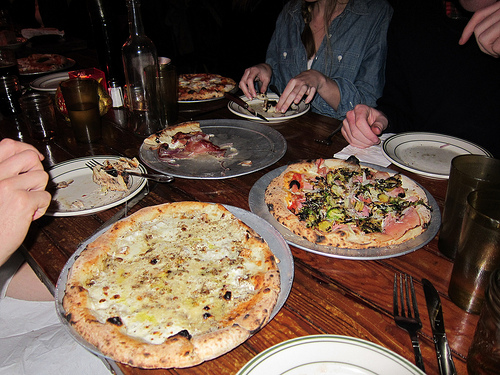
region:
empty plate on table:
[380, 130, 487, 180]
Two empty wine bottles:
[85, 0, 171, 126]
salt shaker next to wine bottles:
[97, 72, 127, 107]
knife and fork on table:
[385, 271, 455, 371]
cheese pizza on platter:
[75, 201, 275, 356]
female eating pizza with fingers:
[225, 2, 375, 129]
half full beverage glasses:
[440, 150, 495, 305]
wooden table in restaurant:
[290, 255, 385, 335]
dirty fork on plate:
[75, 155, 165, 190]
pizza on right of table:
[242, 152, 434, 257]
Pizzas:
[58, 151, 457, 368]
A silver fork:
[392, 264, 431, 373]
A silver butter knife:
[420, 273, 461, 373]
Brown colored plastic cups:
[432, 155, 498, 315]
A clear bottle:
[107, 1, 177, 147]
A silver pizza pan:
[134, 111, 294, 186]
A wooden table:
[292, 250, 379, 331]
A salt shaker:
[103, 76, 128, 114]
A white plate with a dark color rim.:
[380, 114, 495, 187]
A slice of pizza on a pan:
[139, 114, 236, 166]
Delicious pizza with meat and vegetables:
[250, 148, 445, 265]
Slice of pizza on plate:
[135, 111, 289, 186]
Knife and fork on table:
[376, 270, 469, 374]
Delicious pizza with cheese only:
[52, 195, 289, 373]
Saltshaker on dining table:
[100, 72, 130, 118]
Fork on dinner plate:
[50, 131, 175, 220]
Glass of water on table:
[52, 65, 116, 161]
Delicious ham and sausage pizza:
[172, 62, 236, 113]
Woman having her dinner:
[218, 4, 348, 126]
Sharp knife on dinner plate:
[225, 87, 273, 131]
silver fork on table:
[385, 265, 421, 351]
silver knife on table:
[418, 268, 440, 372]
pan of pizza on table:
[76, 222, 274, 356]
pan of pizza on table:
[280, 162, 425, 259]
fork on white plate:
[98, 156, 170, 185]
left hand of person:
[273, 77, 322, 113]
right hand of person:
[232, 64, 274, 109]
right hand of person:
[335, 100, 400, 147]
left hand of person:
[462, 2, 497, 70]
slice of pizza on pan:
[139, 114, 227, 162]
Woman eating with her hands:
[227, 56, 339, 149]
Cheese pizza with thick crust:
[48, 190, 278, 374]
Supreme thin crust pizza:
[244, 132, 444, 275]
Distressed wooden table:
[298, 265, 378, 342]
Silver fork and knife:
[380, 276, 448, 373]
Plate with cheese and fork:
[42, 145, 139, 214]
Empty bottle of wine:
[110, 0, 167, 132]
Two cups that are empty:
[440, 152, 497, 256]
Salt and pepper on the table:
[100, 68, 147, 123]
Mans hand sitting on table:
[335, 97, 405, 176]